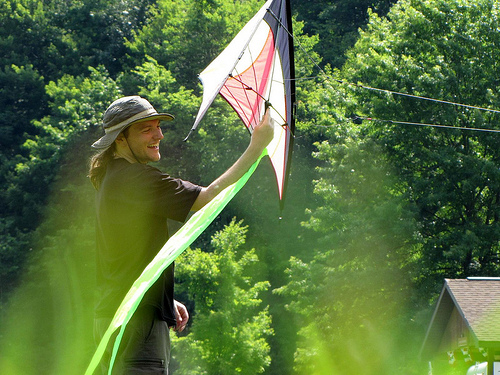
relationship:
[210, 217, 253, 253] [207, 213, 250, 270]
part of a branch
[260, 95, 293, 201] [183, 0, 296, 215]
part of a kite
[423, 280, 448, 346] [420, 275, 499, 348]
edge of roof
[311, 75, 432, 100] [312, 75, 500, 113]
part of a zip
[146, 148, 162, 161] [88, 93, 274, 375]
chin of a man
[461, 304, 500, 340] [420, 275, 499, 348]
part of a roof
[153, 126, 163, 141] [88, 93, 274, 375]
nose of a man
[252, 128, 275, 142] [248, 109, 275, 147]
part of a hand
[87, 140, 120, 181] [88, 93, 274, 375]
hair of man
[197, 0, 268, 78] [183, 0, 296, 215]
edge of kite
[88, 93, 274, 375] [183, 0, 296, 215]
man holding kite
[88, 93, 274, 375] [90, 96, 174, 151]
man wearing a hat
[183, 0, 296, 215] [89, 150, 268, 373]
kite has a tail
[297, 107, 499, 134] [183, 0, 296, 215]
string attached to kite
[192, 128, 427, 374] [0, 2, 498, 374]
trees in background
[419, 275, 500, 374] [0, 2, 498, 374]
building in background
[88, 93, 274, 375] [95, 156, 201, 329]
man wears top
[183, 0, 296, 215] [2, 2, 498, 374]
kite in air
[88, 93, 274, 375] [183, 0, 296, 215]
man holds kite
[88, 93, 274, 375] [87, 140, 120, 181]
man has hair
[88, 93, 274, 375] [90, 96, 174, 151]
man wearing hat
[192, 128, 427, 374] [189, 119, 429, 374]
trees full of leaves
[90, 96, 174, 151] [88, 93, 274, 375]
hat tied to man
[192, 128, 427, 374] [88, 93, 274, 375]
trees behind man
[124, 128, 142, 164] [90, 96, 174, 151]
strap on hat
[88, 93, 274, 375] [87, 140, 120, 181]
man has long hair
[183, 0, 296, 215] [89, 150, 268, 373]
kite has tail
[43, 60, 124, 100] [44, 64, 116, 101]
sunlight shining on leaves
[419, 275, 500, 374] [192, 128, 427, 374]
building among trees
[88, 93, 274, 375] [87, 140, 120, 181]
man with hair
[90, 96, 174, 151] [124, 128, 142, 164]
hat with strap